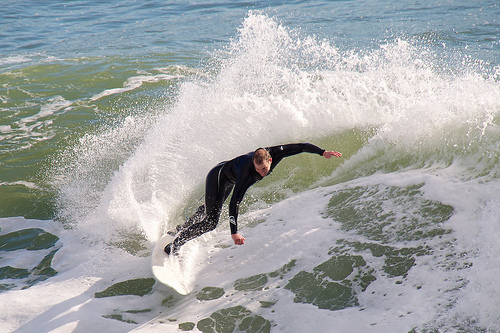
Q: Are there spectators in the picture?
A: No, there are no spectators.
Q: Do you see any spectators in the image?
A: No, there are no spectators.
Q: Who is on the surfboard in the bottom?
A: The man is on the surf board.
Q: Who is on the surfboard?
A: The man is on the surf board.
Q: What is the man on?
A: The man is on the surfboard.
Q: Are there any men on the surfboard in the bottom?
A: Yes, there is a man on the surfboard.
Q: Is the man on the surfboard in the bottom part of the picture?
A: Yes, the man is on the surfboard.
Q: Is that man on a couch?
A: No, the man is on the surfboard.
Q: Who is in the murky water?
A: The man is in the water.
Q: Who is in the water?
A: The man is in the water.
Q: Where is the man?
A: The man is in the water.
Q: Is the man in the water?
A: Yes, the man is in the water.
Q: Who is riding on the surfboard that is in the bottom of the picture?
A: The man is riding on the surfboard.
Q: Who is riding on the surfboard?
A: The man is riding on the surfboard.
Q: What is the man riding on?
A: The man is riding on the surfboard.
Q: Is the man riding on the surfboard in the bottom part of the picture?
A: Yes, the man is riding on the surfboard.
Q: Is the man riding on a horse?
A: No, the man is riding on the surfboard.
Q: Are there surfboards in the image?
A: Yes, there is a surfboard.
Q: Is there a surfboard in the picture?
A: Yes, there is a surfboard.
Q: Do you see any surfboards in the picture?
A: Yes, there is a surfboard.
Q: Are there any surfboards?
A: Yes, there is a surfboard.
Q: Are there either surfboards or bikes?
A: Yes, there is a surfboard.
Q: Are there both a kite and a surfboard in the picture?
A: No, there is a surfboard but no kites.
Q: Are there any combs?
A: No, there are no combs.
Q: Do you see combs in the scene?
A: No, there are no combs.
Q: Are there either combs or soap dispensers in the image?
A: No, there are no combs or soap dispensers.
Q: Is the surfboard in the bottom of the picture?
A: Yes, the surfboard is in the bottom of the image.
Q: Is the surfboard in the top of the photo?
A: No, the surfboard is in the bottom of the image.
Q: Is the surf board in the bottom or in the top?
A: The surf board is in the bottom of the image.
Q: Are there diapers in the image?
A: No, there are no diapers.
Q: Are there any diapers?
A: No, there are no diapers.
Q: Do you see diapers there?
A: No, there are no diapers.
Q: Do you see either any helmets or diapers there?
A: No, there are no diapers or helmets.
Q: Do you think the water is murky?
A: Yes, the water is murky.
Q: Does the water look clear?
A: No, the water is murky.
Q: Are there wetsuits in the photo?
A: Yes, there is a wetsuit.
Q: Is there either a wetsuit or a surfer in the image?
A: Yes, there is a wetsuit.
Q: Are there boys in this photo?
A: No, there are no boys.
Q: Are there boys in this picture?
A: No, there are no boys.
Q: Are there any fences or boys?
A: No, there are no boys or fences.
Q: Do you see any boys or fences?
A: No, there are no boys or fences.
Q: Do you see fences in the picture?
A: No, there are no fences.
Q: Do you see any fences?
A: No, there are no fences.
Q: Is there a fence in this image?
A: No, there are no fences.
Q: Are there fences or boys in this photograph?
A: No, there are no fences or boys.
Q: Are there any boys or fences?
A: No, there are no fences or boys.